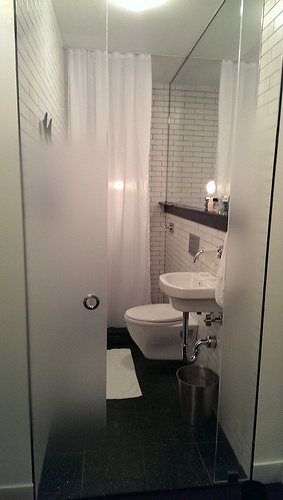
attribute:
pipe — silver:
[179, 310, 219, 364]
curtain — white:
[62, 47, 153, 328]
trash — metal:
[172, 360, 220, 435]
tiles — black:
[50, 342, 237, 485]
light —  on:
[107, 0, 168, 12]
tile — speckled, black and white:
[132, 409, 195, 444]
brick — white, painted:
[140, 102, 182, 310]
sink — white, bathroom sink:
[156, 246, 264, 319]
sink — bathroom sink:
[159, 270, 222, 311]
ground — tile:
[73, 324, 241, 481]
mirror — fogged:
[13, 2, 257, 493]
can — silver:
[186, 372, 213, 434]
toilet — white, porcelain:
[122, 303, 198, 361]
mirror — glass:
[165, 78, 239, 208]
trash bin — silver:
[172, 362, 222, 431]